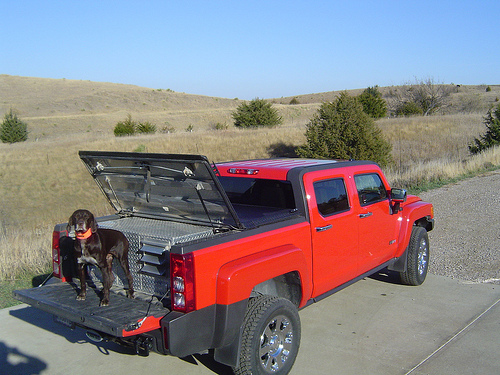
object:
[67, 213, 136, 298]
dog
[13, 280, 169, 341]
tailgate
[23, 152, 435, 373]
truck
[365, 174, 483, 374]
road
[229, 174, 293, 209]
window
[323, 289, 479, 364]
concrete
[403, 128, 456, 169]
grass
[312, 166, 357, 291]
doors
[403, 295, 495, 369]
crack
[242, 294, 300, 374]
tire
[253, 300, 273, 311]
grooves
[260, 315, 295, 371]
rims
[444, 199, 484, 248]
gravel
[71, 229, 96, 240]
collar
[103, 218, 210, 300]
tool box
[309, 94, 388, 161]
tree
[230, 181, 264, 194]
tint